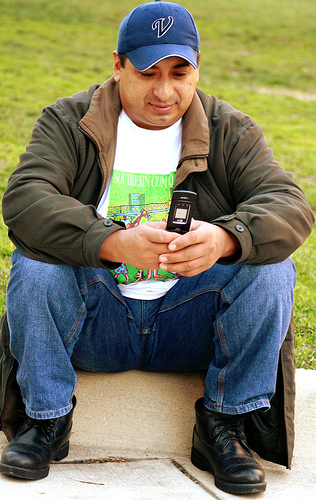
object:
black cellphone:
[165, 190, 198, 236]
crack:
[66, 449, 226, 498]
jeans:
[5, 247, 298, 420]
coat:
[0, 74, 315, 470]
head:
[111, 0, 201, 129]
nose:
[153, 68, 174, 102]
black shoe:
[190, 396, 266, 496]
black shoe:
[0, 411, 72, 483]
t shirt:
[95, 107, 183, 302]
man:
[0, 0, 314, 496]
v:
[151, 15, 175, 38]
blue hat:
[115, 0, 200, 75]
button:
[235, 224, 245, 233]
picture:
[105, 167, 181, 285]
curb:
[70, 366, 315, 471]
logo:
[151, 16, 174, 39]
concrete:
[0, 441, 315, 499]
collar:
[76, 76, 211, 206]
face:
[119, 57, 198, 128]